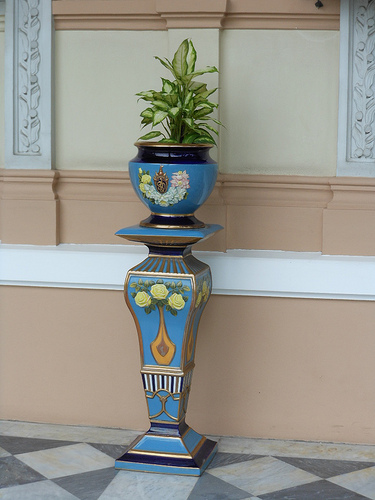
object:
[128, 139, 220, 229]
vase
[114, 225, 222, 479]
stand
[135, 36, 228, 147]
plant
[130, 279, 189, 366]
flower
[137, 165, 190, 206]
flower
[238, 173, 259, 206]
molding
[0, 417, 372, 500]
floor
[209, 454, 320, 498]
tile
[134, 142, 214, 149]
crest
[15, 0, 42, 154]
design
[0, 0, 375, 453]
wall